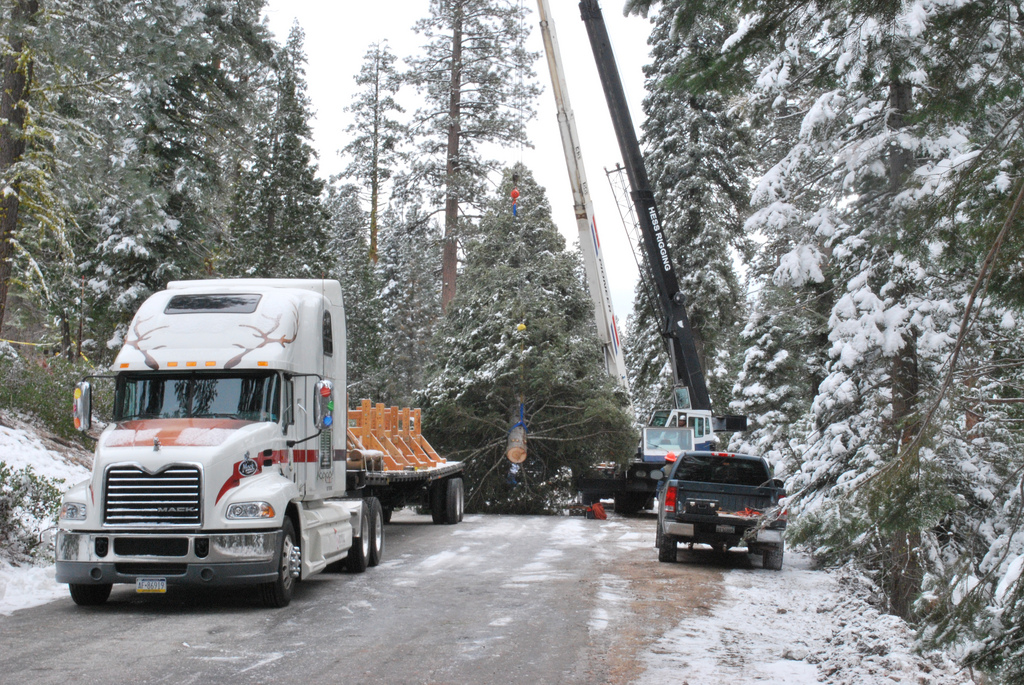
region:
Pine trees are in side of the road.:
[52, 23, 954, 523]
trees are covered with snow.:
[26, 50, 916, 439]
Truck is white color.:
[45, 264, 464, 603]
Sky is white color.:
[304, 4, 655, 267]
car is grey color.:
[643, 445, 793, 570]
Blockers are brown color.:
[339, 387, 451, 482]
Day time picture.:
[58, 69, 907, 640]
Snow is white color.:
[700, 555, 850, 660]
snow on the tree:
[784, 255, 805, 269]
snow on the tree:
[927, 452, 969, 478]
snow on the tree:
[122, 234, 160, 248]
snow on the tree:
[920, 168, 955, 197]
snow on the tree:
[487, 361, 507, 374]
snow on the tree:
[980, 174, 1012, 190]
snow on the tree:
[806, 424, 836, 440]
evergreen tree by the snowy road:
[412, 163, 637, 512]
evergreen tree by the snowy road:
[232, 55, 319, 283]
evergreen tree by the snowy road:
[339, 36, 390, 242]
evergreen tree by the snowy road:
[386, 0, 532, 310]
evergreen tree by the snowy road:
[138, 8, 260, 266]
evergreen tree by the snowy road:
[0, 2, 108, 369]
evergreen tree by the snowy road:
[627, 4, 764, 456]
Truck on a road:
[49, 256, 476, 614]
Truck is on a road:
[52, 267, 477, 619]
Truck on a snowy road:
[62, 231, 481, 623]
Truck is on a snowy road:
[32, 263, 484, 608]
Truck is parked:
[645, 444, 808, 581]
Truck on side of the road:
[631, 433, 805, 583]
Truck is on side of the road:
[633, 431, 824, 577]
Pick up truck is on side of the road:
[633, 433, 798, 577]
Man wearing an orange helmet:
[658, 440, 682, 467]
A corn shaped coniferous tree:
[487, 213, 551, 392]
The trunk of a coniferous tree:
[511, 419, 525, 448]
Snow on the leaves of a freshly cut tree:
[463, 340, 543, 367]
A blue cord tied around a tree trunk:
[514, 409, 527, 426]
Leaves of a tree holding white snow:
[840, 305, 907, 350]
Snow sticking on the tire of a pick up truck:
[771, 551, 782, 565]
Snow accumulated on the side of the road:
[764, 596, 859, 682]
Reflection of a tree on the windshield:
[183, 377, 212, 413]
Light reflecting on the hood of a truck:
[126, 424, 216, 441]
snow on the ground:
[679, 537, 913, 680]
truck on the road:
[39, 263, 473, 621]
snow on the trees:
[614, 22, 1006, 596]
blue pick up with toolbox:
[646, 433, 806, 579]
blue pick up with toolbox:
[645, 430, 798, 582]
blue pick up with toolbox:
[633, 421, 804, 570]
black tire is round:
[261, 518, 303, 601]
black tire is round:
[347, 507, 373, 571]